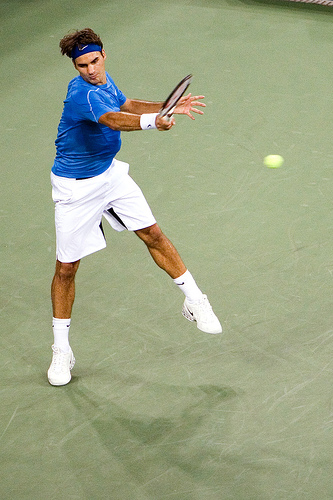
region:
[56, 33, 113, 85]
Man wearing blue head band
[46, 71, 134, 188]
Man wearing blue shirt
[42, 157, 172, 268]
Man wearing white shorts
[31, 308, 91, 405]
Man wearing a white shoe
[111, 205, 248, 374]
Man with his foot in the air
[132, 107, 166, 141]
Man wearing white wrist band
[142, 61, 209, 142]
Man swinging a tennis racket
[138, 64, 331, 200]
Man hitting a tennis ball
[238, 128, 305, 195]
A tennis ball in flight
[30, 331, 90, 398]
White shoe on a green surface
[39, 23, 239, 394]
man playing tennis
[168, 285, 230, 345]
foot lifted off the ground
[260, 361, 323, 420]
white scuff mark on the tennis court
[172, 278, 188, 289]
black logo on the sock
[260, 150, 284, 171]
small yellow tennis ball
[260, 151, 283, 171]
tennis ball in the air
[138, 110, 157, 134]
thick white band around the arm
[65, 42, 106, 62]
dark blue sweatband on the head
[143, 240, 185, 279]
muscle definition on the leg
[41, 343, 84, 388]
bright white tennis shoe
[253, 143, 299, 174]
A yellow tennis ball.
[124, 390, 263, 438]
Green court for playing tennis.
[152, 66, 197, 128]
Man holding a tennis racket.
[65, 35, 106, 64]
Tennis player with a blue headband.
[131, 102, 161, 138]
A white wrist band.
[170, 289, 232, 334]
Tennis player wearing white sneakers.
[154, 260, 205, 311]
Man wearing Nike socks.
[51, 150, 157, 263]
Wearing white shorts for tennis.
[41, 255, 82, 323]
A man's hairy leg.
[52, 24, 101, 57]
Tennis player with floppy brown hair.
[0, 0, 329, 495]
A green tennis court.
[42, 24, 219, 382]
A tennis player.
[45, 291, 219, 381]
White tennis shoes with a black check on the sides.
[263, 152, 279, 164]
A tennis ball.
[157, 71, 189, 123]
A tennis racket.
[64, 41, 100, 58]
A blue headband.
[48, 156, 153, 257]
White and black sports shorts.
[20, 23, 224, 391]
A man swinging a tennis racket.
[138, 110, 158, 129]
A white wristband.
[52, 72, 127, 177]
A short sleeve blue shirt.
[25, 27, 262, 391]
This is a person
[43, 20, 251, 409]
This is a man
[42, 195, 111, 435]
Leg of a person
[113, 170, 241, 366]
Leg of a person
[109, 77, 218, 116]
Hand of a person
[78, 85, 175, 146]
Hand of a person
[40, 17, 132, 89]
Head of a person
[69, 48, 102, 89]
FAce of a person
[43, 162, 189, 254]
A pair of white shorts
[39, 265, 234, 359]
A pair of white socks